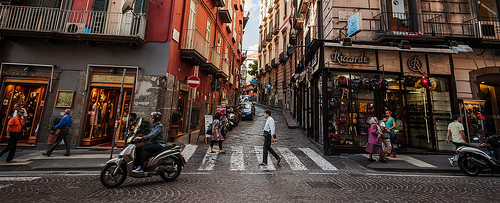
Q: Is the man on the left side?
A: Yes, the man is on the left of the image.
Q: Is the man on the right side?
A: No, the man is on the left of the image.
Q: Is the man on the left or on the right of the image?
A: The man is on the left of the image.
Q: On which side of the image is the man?
A: The man is on the left of the image.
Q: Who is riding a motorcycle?
A: The man is riding a motorcycle.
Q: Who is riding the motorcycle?
A: The man is riding a motorcycle.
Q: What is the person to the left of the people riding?
A: The man is riding a motorcycle.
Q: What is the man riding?
A: The man is riding a motorcycle.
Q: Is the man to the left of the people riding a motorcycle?
A: Yes, the man is riding a motorcycle.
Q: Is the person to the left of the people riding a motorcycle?
A: Yes, the man is riding a motorcycle.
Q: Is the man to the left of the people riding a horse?
A: No, the man is riding a motorcycle.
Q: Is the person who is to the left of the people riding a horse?
A: No, the man is riding a motorcycle.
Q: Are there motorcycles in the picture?
A: Yes, there is a motorcycle.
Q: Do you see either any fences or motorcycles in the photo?
A: Yes, there is a motorcycle.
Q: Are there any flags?
A: No, there are no flags.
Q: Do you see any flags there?
A: No, there are no flags.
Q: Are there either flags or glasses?
A: No, there are no flags or glasses.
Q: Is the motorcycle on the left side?
A: Yes, the motorcycle is on the left of the image.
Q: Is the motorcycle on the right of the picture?
A: No, the motorcycle is on the left of the image.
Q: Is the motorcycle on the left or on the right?
A: The motorcycle is on the left of the image.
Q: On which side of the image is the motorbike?
A: The motorbike is on the left of the image.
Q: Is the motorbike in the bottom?
A: Yes, the motorbike is in the bottom of the image.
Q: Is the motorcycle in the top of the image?
A: No, the motorcycle is in the bottom of the image.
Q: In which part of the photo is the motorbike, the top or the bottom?
A: The motorbike is in the bottom of the image.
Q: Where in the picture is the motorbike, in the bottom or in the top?
A: The motorbike is in the bottom of the image.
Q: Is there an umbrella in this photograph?
A: No, there are no umbrellas.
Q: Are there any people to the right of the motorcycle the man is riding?
A: Yes, there are people to the right of the motorbike.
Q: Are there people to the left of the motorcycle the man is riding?
A: No, the people are to the right of the motorcycle.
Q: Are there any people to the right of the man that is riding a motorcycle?
A: Yes, there are people to the right of the man.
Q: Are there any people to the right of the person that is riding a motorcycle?
A: Yes, there are people to the right of the man.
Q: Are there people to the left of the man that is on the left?
A: No, the people are to the right of the man.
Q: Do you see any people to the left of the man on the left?
A: No, the people are to the right of the man.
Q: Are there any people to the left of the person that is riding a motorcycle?
A: No, the people are to the right of the man.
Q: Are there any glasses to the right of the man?
A: No, there are people to the right of the man.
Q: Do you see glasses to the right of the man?
A: No, there are people to the right of the man.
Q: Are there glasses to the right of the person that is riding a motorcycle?
A: No, there are people to the right of the man.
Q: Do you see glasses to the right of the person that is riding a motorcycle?
A: No, there are people to the right of the man.